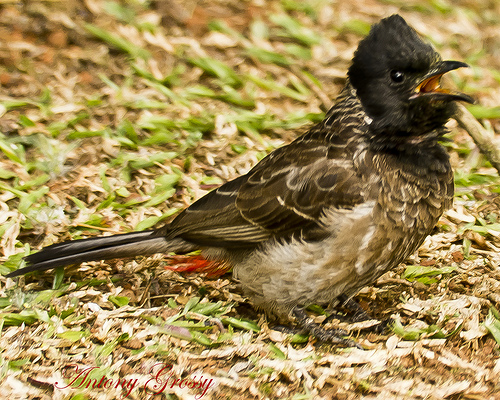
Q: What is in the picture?
A: A bird.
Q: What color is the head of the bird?
A: Black.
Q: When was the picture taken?
A: In the daytime.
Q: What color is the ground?
A: Brown and white.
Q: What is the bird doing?
A: Standing.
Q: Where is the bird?
A: Outside on the ground.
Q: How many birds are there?
A: One.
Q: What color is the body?
A: Brown.